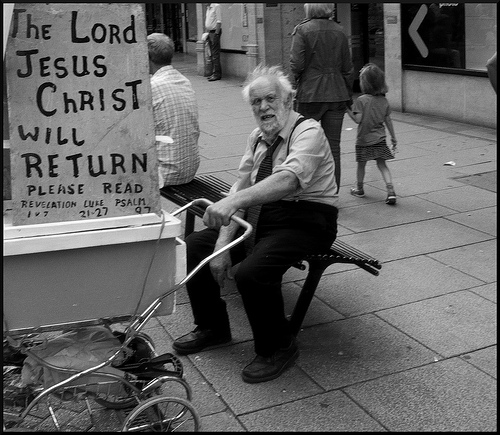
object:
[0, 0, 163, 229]
cardboard sign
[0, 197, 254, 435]
cart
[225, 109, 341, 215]
shirt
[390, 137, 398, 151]
hands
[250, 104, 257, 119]
facial hair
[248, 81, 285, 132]
face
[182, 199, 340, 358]
pants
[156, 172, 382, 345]
bench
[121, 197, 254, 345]
handle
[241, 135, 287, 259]
tie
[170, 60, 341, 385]
man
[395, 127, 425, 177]
ground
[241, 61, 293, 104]
hair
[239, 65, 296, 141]
head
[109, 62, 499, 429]
sidewalk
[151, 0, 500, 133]
building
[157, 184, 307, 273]
edge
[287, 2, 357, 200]
woman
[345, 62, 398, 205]
girl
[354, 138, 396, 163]
skirt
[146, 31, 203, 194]
man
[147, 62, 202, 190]
checkered shirt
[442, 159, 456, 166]
trash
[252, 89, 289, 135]
beard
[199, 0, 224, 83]
person standing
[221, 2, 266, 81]
wall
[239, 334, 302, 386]
shoe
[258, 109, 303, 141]
neck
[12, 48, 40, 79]
letter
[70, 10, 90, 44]
letter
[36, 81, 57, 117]
letter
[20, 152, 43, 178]
letter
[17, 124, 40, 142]
letter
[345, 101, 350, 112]
girl's hand